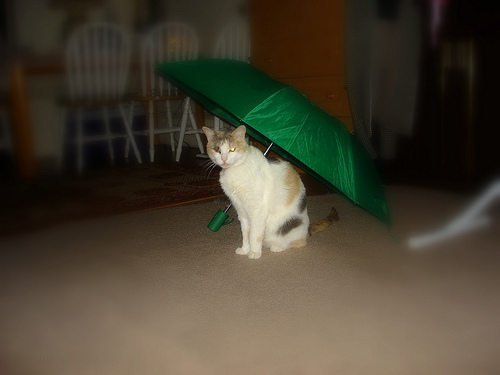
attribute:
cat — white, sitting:
[192, 115, 345, 257]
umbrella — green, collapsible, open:
[152, 44, 397, 228]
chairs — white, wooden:
[56, 14, 246, 162]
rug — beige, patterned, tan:
[3, 189, 500, 372]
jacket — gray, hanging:
[372, 4, 421, 133]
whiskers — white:
[191, 156, 261, 175]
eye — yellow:
[228, 143, 236, 151]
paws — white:
[228, 241, 289, 259]